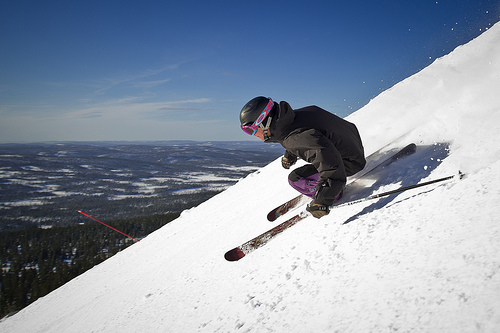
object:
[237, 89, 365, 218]
skier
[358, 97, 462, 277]
snow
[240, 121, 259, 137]
goggles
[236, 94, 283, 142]
head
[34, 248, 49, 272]
tree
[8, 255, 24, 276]
tree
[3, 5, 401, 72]
sky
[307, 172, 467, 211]
pole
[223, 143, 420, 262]
skis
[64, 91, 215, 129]
clouds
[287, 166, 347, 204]
pants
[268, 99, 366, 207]
jacket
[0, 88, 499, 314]
hill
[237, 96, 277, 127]
hat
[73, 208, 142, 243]
pole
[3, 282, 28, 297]
bottom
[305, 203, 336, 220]
glove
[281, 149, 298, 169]
hand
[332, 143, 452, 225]
shadow